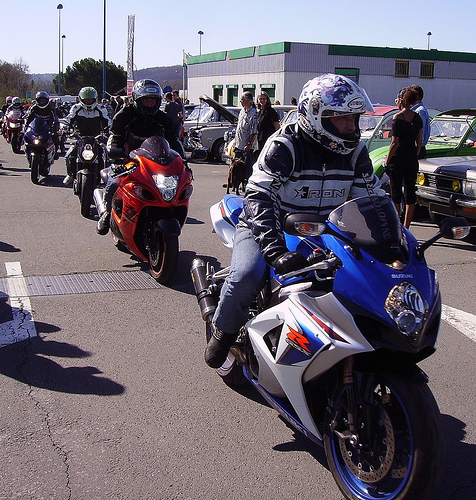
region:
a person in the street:
[373, 74, 421, 230]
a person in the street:
[401, 68, 435, 144]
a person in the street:
[224, 85, 260, 176]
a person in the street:
[251, 86, 282, 144]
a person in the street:
[194, 59, 386, 372]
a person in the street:
[94, 72, 177, 227]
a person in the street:
[162, 89, 185, 127]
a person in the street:
[171, 88, 188, 109]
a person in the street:
[64, 82, 108, 177]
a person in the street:
[21, 88, 60, 162]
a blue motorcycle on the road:
[199, 159, 447, 498]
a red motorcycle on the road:
[97, 138, 190, 270]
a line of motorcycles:
[5, 81, 407, 411]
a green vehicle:
[365, 77, 475, 159]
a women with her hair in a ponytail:
[384, 84, 430, 203]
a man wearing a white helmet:
[273, 46, 391, 167]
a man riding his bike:
[174, 74, 462, 411]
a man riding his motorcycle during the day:
[180, 65, 445, 485]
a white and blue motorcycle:
[163, 187, 431, 412]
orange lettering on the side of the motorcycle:
[273, 306, 319, 379]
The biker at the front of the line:
[191, 62, 441, 498]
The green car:
[363, 108, 475, 218]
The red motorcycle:
[94, 139, 196, 281]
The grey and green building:
[182, 37, 474, 128]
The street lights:
[53, 2, 435, 121]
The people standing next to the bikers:
[165, 84, 432, 231]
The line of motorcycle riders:
[3, 71, 450, 495]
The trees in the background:
[0, 52, 131, 108]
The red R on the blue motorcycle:
[283, 323, 314, 352]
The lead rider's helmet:
[291, 69, 374, 155]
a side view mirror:
[431, 208, 474, 244]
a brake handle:
[276, 249, 338, 285]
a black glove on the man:
[271, 246, 305, 279]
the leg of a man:
[194, 224, 270, 370]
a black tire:
[315, 341, 447, 496]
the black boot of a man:
[196, 328, 241, 371]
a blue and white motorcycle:
[189, 179, 461, 498]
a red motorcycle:
[73, 129, 198, 282]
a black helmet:
[122, 75, 169, 126]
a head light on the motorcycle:
[152, 169, 181, 209]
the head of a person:
[128, 71, 166, 112]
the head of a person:
[237, 87, 258, 110]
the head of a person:
[253, 86, 270, 103]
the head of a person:
[393, 85, 414, 106]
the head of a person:
[406, 81, 425, 100]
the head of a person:
[286, 90, 302, 104]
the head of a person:
[160, 89, 176, 105]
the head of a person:
[170, 84, 183, 100]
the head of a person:
[77, 77, 99, 113]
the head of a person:
[24, 80, 53, 116]